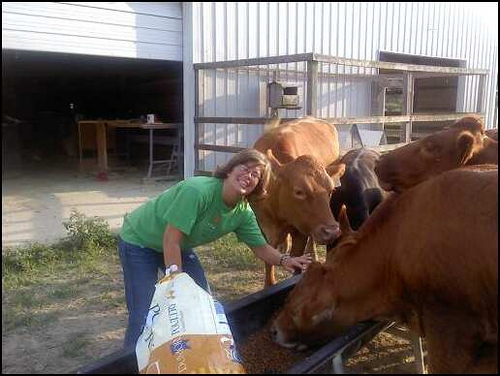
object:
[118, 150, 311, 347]
lady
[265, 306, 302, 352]
feed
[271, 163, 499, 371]
cow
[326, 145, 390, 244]
cow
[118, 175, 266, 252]
shirt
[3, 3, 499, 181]
building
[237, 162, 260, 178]
glasses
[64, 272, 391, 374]
feed bin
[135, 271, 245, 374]
bag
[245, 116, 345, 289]
cow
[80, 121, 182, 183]
table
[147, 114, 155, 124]
mug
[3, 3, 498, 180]
barn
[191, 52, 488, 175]
bird house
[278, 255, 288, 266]
bracelet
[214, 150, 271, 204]
hair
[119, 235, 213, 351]
jeans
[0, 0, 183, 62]
door